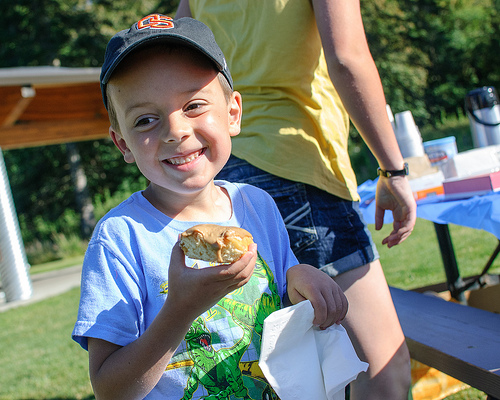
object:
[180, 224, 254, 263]
donut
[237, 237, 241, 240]
frosting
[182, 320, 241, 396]
dinosaur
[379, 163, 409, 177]
watch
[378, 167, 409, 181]
wrist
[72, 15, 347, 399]
boy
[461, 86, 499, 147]
thermos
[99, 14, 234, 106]
cap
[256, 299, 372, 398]
napkin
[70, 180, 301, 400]
shirt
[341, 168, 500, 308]
table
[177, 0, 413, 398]
person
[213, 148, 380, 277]
shorts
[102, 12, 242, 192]
head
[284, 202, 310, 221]
stripe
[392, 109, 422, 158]
cup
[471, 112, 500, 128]
handle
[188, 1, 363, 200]
top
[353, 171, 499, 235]
cover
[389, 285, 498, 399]
bench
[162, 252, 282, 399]
design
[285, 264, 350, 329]
hand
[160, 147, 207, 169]
smile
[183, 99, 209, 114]
eye